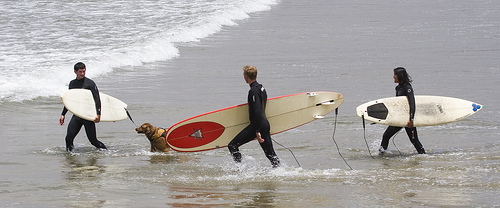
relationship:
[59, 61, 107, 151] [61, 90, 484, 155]
surfer with surfboards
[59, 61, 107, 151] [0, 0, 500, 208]
surfer walking in ocean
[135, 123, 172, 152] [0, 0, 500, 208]
dog in ocean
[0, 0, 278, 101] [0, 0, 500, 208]
wave in ocean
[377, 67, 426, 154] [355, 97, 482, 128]
woman holding surboard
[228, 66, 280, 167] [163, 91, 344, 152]
man holding surfboard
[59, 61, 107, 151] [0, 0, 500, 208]
surfer are standing in ocean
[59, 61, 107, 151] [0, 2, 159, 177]
surfer walking into ocean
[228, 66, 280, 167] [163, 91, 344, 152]
man with surfboard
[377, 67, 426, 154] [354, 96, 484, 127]
woman holding surfboard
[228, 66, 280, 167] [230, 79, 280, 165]
man wearing a wetsuit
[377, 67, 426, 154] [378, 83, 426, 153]
woman wearing a wetsuit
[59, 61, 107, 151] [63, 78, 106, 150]
surfer wearing a wetsuit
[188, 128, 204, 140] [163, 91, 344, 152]
logo on surfboard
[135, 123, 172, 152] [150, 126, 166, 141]
dog wearing a harness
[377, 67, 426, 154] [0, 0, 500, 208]
woman walking in ocean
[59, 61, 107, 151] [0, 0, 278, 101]
surfer walking towards wave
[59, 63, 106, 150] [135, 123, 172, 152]
surfer has a dog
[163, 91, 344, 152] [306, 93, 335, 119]
surfboard has fins